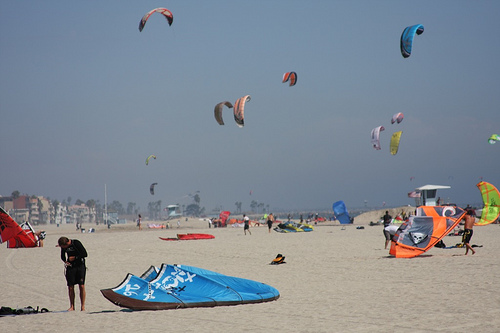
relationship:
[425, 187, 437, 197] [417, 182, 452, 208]
window on lifeguard tower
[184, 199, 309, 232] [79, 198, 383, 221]
objects on distance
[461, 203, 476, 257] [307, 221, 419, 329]
man on beach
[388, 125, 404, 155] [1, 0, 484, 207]
kite flying in sky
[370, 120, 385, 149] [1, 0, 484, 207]
kite flying in sky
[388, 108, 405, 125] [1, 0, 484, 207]
kite flying in sky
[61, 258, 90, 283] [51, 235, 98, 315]
shorts on a man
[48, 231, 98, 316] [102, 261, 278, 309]
person preparing parachute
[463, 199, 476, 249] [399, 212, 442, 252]
man holding kite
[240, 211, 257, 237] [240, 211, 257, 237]
outfit wearing outfit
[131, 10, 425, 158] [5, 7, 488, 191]
paraglider are in sky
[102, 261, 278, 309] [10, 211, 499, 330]
parachute on sand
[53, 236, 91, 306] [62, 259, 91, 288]
man wearing shorts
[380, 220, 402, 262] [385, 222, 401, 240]
man wearing shirt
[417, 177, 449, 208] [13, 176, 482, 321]
lifeguard tower on beach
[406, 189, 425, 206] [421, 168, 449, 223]
flag on lifeguard tower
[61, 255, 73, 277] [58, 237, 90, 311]
something with man